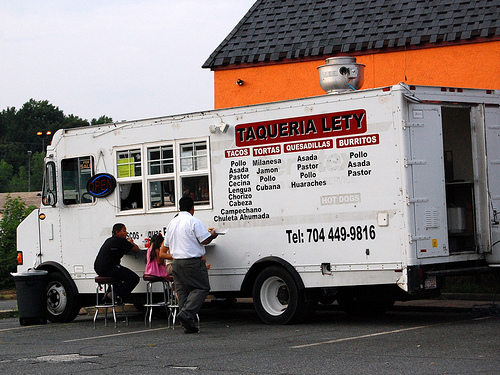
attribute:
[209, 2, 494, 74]
roof — dark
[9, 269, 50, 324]
trash can — green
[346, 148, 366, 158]
word — black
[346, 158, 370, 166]
word — black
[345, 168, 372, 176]
word — black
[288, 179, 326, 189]
word — black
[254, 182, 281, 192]
word — black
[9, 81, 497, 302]
truck — white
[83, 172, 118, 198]
sign — OPEN, red, black, blue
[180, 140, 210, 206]
window — ordering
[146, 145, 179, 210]
window — ordering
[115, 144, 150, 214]
window — ordering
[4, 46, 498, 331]
truck — food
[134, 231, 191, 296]
girl — little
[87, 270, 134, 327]
stool — metal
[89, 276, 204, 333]
stools — metal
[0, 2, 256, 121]
sky — cloud-covered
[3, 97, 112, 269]
leaves — green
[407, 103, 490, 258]
door — open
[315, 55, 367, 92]
exhaust fan — roof-mounted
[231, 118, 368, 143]
sign — red, black, white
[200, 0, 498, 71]
roof — slanted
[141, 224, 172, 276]
girl — little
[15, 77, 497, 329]
truck — food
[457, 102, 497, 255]
door — open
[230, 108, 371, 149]
sign — red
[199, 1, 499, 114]
building — orange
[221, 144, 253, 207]
menu items — taco